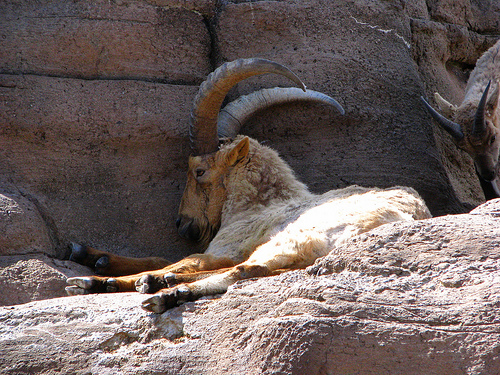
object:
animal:
[65, 58, 431, 312]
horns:
[190, 57, 347, 155]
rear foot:
[141, 283, 191, 316]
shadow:
[152, 301, 195, 340]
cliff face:
[0, 197, 499, 374]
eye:
[192, 167, 206, 178]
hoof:
[64, 276, 113, 297]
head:
[176, 135, 306, 243]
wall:
[0, 0, 490, 263]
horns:
[418, 78, 490, 146]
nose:
[175, 212, 186, 236]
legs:
[190, 236, 300, 294]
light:
[0, 193, 499, 360]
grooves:
[271, 309, 499, 341]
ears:
[232, 135, 250, 162]